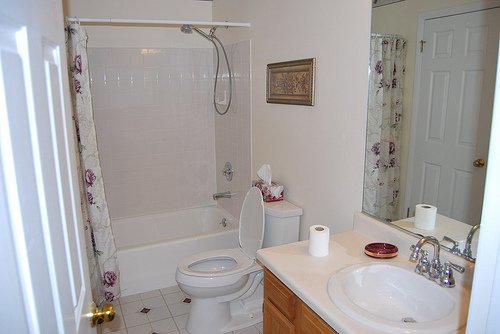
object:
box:
[252, 180, 284, 203]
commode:
[175, 187, 303, 334]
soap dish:
[364, 242, 399, 259]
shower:
[180, 24, 213, 40]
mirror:
[361, 0, 500, 264]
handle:
[90, 304, 116, 328]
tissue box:
[252, 180, 285, 203]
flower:
[85, 169, 97, 189]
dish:
[364, 242, 399, 259]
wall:
[288, 124, 368, 182]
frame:
[266, 58, 316, 106]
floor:
[115, 285, 263, 334]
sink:
[342, 265, 456, 323]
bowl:
[340, 265, 454, 323]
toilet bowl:
[175, 187, 303, 334]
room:
[3, 2, 496, 332]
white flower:
[77, 95, 92, 118]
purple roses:
[102, 271, 117, 288]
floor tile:
[118, 293, 173, 326]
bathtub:
[110, 204, 239, 298]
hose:
[211, 37, 232, 115]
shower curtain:
[64, 24, 121, 308]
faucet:
[410, 236, 466, 288]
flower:
[375, 60, 383, 75]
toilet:
[0, 0, 500, 334]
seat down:
[176, 249, 250, 279]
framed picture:
[269, 65, 310, 100]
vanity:
[249, 234, 378, 332]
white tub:
[110, 204, 240, 298]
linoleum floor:
[123, 298, 179, 328]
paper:
[257, 163, 272, 185]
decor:
[266, 57, 316, 106]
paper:
[308, 225, 330, 257]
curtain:
[64, 24, 121, 306]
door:
[0, 1, 115, 334]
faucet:
[213, 191, 231, 200]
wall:
[249, 0, 347, 174]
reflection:
[361, 0, 500, 260]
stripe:
[364, 250, 398, 259]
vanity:
[260, 0, 497, 329]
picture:
[262, 59, 318, 107]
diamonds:
[140, 308, 150, 314]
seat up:
[168, 172, 270, 300]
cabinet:
[256, 259, 337, 334]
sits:
[177, 250, 254, 277]